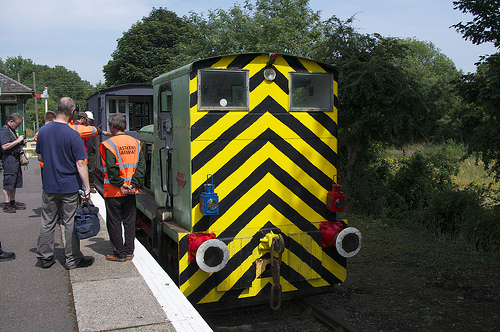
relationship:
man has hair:
[100, 114, 145, 262] [108, 112, 127, 132]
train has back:
[75, 54, 365, 314] [179, 52, 362, 305]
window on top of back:
[200, 67, 247, 112] [179, 52, 362, 305]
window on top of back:
[289, 72, 334, 112] [179, 52, 362, 305]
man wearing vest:
[100, 114, 145, 262] [100, 133, 142, 198]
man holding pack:
[36, 97, 95, 270] [73, 199, 99, 240]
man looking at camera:
[2, 114, 28, 214] [21, 132, 25, 142]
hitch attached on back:
[257, 231, 286, 311] [179, 52, 362, 305]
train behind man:
[75, 54, 365, 314] [100, 114, 145, 262]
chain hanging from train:
[272, 260, 280, 313] [75, 54, 365, 314]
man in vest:
[72, 112, 98, 176] [74, 124, 98, 153]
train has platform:
[75, 54, 365, 314] [2, 157, 216, 332]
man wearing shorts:
[2, 114, 28, 214] [3, 157, 23, 191]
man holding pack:
[2, 114, 28, 214] [19, 148, 28, 167]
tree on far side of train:
[321, 19, 419, 182] [75, 54, 365, 314]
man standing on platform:
[100, 114, 145, 262] [2, 157, 216, 332]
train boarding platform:
[75, 54, 365, 314] [2, 157, 216, 332]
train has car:
[75, 54, 365, 314] [89, 83, 153, 194]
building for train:
[1, 71, 33, 145] [75, 54, 365, 314]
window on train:
[109, 99, 116, 114] [75, 54, 365, 314]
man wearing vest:
[72, 112, 98, 176] [74, 124, 98, 153]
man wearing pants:
[100, 114, 145, 262] [104, 199, 136, 255]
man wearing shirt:
[36, 97, 95, 270] [34, 122, 88, 194]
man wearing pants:
[36, 97, 95, 270] [38, 194, 84, 271]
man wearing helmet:
[83, 110, 97, 128] [86, 110, 92, 120]